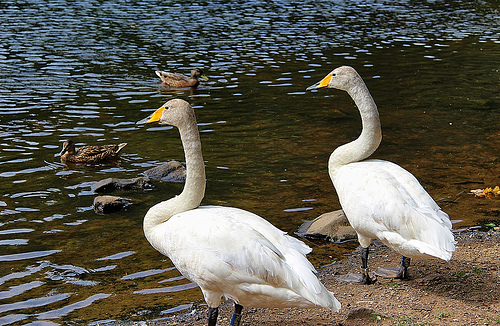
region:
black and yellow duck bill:
[296, 67, 335, 95]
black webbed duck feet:
[338, 252, 418, 292]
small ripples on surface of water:
[224, 5, 303, 58]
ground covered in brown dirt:
[395, 290, 466, 322]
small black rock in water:
[26, 257, 107, 295]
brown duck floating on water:
[43, 122, 130, 175]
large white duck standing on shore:
[302, 48, 452, 319]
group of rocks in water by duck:
[85, 157, 185, 224]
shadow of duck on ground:
[399, 256, 494, 306]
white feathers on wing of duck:
[190, 222, 270, 284]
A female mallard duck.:
[57, 138, 127, 168]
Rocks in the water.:
[90, 157, 193, 215]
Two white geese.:
[135, 65, 458, 324]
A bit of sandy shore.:
[102, 224, 497, 324]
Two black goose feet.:
[334, 242, 414, 286]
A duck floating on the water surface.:
[154, 65, 211, 90]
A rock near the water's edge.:
[295, 204, 358, 245]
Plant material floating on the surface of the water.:
[469, 185, 499, 200]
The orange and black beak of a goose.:
[302, 70, 332, 92]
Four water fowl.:
[58, 65, 458, 324]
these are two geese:
[105, 29, 455, 324]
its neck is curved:
[298, 35, 417, 182]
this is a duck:
[2, 113, 146, 167]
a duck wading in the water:
[34, 110, 146, 195]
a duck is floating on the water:
[140, 48, 228, 94]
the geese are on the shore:
[115, 42, 475, 322]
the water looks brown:
[215, 92, 306, 164]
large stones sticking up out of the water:
[62, 148, 224, 230]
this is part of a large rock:
[271, 167, 348, 244]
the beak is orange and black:
[127, 98, 169, 126]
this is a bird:
[108, 186, 290, 291]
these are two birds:
[193, 180, 449, 230]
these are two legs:
[171, 287, 249, 321]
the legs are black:
[178, 270, 266, 324]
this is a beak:
[130, 115, 172, 134]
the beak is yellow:
[146, 111, 161, 124]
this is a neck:
[166, 166, 217, 195]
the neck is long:
[165, 151, 227, 207]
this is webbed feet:
[335, 253, 381, 309]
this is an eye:
[149, 91, 194, 122]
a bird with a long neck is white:
[133, 96, 345, 324]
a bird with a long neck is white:
[303, 62, 460, 284]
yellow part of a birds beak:
[315, 74, 331, 89]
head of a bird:
[302, 64, 359, 96]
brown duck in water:
[57, 136, 127, 169]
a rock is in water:
[93, 165, 178, 212]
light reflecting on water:
[0, 1, 495, 111]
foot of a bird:
[330, 247, 382, 287]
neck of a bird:
[144, 127, 206, 232]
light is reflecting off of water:
[0, 131, 108, 324]